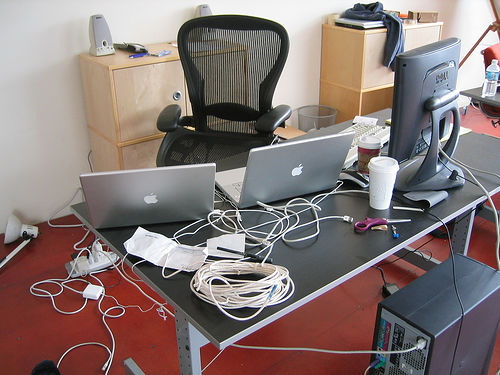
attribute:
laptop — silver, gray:
[242, 140, 355, 199]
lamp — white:
[5, 211, 41, 251]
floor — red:
[304, 317, 344, 335]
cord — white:
[196, 266, 286, 304]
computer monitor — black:
[397, 49, 465, 107]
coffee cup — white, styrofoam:
[362, 150, 401, 214]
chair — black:
[184, 26, 287, 111]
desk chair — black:
[166, 7, 283, 137]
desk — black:
[475, 135, 491, 166]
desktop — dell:
[385, 38, 470, 191]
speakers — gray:
[86, 11, 123, 57]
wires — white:
[313, 187, 363, 254]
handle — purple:
[354, 215, 386, 231]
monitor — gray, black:
[80, 171, 217, 214]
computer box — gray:
[380, 277, 483, 335]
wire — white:
[268, 211, 319, 244]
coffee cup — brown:
[354, 136, 371, 169]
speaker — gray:
[189, 1, 217, 14]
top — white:
[357, 135, 385, 150]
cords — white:
[313, 190, 339, 213]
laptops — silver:
[70, 152, 346, 200]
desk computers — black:
[291, 37, 493, 227]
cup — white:
[363, 155, 399, 185]